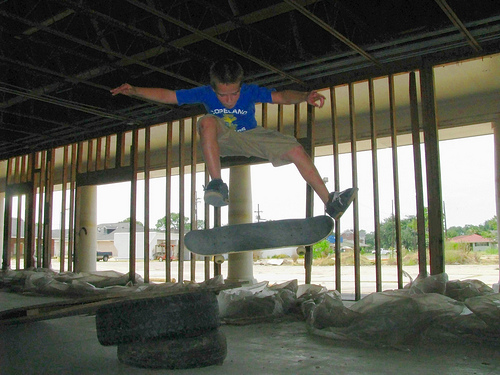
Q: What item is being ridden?
A: A skateboard.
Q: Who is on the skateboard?
A: A rider.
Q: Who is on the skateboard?
A: A boy.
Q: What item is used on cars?
A: Tires.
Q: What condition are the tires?
A: Dirty.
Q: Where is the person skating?
A: A building.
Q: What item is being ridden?
A: A skateboard.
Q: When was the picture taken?
A: Daytime.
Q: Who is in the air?
A: Kid.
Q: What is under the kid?
A: Skateboard.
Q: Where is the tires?
A: To the left of the kid.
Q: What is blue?
A: Shirt.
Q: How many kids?
A: One.